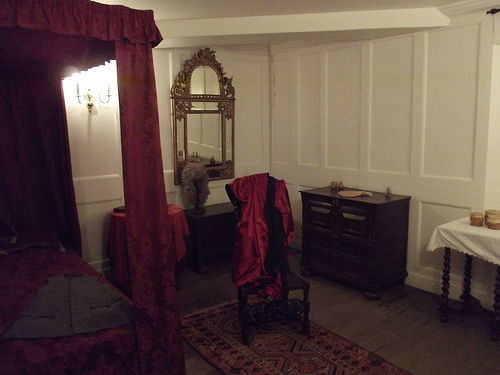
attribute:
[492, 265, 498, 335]
leg — turned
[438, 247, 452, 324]
leg — turned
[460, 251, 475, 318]
leg — turned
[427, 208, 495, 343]
table — small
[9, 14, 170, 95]
canopy — red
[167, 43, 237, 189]
mirror — gold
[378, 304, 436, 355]
floor — wood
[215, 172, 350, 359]
chair — indoors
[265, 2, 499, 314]
wall — white, plain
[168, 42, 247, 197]
mirror — gold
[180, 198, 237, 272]
cabinet — brown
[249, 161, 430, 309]
dresser — small, brown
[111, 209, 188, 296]
cloth — table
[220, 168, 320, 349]
chair — brown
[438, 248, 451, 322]
stick — brown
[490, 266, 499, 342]
stick — brown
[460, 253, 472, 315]
stick — brown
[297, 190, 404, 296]
dresser — brown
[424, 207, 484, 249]
tablecloth — white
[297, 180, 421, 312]
dresser — small